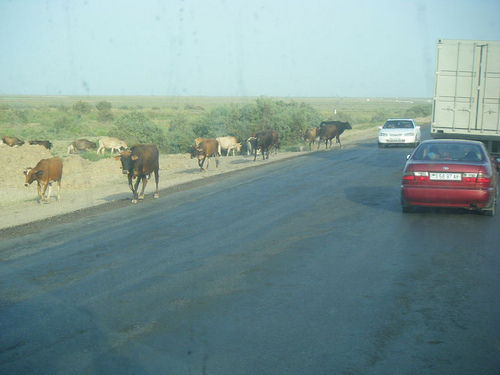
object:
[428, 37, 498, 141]
trailer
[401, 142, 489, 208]
back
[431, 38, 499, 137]
back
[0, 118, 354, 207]
herd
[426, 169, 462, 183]
number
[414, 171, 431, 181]
light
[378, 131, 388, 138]
headlight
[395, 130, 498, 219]
car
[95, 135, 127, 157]
cow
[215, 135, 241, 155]
cow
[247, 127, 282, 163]
cow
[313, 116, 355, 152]
cow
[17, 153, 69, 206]
cow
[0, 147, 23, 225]
dirt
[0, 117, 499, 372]
highway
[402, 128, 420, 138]
headlight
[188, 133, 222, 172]
cow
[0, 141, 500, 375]
road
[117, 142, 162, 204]
cow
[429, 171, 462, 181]
license plate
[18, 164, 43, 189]
head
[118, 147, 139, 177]
head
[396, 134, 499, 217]
red car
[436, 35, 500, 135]
doors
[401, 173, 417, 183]
headlights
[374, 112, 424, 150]
car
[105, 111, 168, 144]
bush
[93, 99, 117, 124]
bush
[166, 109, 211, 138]
bush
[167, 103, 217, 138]
bush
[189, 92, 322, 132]
bush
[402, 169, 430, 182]
taillight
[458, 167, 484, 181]
taillight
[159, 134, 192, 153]
bush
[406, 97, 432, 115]
tree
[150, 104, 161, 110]
tree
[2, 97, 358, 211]
cattle herd